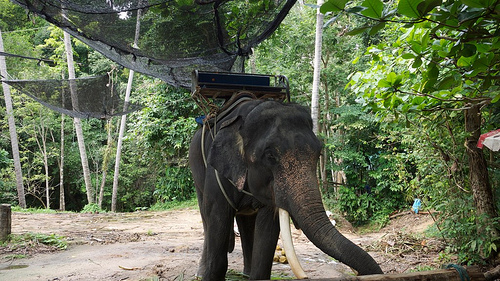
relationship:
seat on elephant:
[191, 67, 292, 119] [187, 96, 385, 279]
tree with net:
[318, 5, 498, 253] [10, 0, 301, 93]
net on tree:
[10, 0, 301, 93] [318, 5, 498, 253]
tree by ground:
[318, 5, 498, 253] [3, 205, 460, 278]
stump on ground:
[0, 87, 27, 207] [3, 205, 460, 278]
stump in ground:
[0, 87, 27, 207] [3, 205, 460, 278]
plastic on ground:
[444, 261, 470, 278] [3, 205, 460, 278]